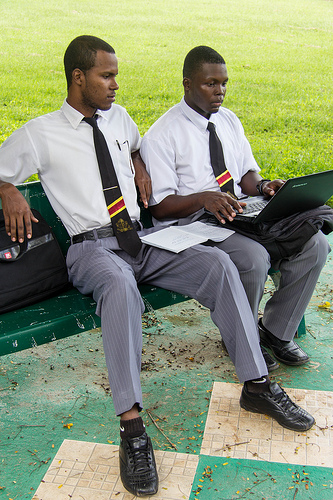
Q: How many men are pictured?
A: Two.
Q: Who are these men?
A: Students.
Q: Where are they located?
A: On a bench.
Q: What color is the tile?
A: Green and white.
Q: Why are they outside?
A: Studying.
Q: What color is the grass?
A: Green.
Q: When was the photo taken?
A: Daylight hours.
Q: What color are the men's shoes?
A: Black.